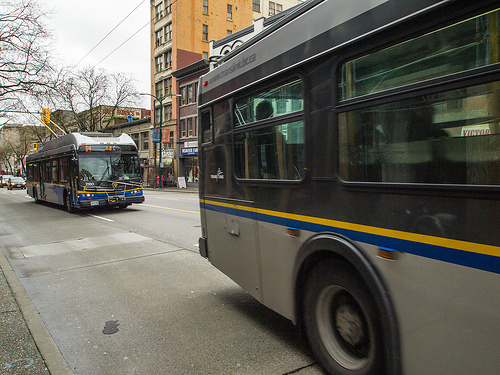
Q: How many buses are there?
A: Two.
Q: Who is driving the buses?
A: Bus drivers.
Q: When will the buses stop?
A: When they have reached the bus station.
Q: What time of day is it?
A: Daytime.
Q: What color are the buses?
A: White, blue and yellow.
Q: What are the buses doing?
A: Moving down the road.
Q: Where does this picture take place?
A: On a public road.